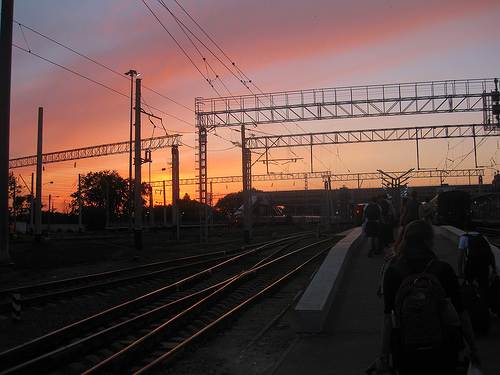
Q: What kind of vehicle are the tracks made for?
A: Train.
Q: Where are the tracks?
A: Ground.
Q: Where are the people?
A: Train platform.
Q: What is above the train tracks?
A: Power lines.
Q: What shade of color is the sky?
A: Pink and grey.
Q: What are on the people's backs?
A: Backpacks.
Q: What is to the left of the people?
A: Train tracks.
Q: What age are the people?
A: Tennagers.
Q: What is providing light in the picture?
A: The sun.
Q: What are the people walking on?
A: Sidewalk.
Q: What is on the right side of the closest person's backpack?
A: Water.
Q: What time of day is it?
A: Early morning.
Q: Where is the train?
A: Top right.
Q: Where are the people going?
A: To the train station.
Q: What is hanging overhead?
A: Wires, metal, lights.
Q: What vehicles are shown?
A: Train.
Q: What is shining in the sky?
A: Sunlight.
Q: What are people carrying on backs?
A: Backpacks.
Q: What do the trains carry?
A: Passengers.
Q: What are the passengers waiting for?
A: Train.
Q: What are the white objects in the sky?
A: Clouds.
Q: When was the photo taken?
A: At dusk.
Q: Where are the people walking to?
A: Train.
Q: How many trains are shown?
A: 1.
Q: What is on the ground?
A: Train tracks.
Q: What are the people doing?
A: Walking.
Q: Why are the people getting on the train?
A: To travel.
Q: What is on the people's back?
A: Backpack.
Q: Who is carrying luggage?
A: People walking.